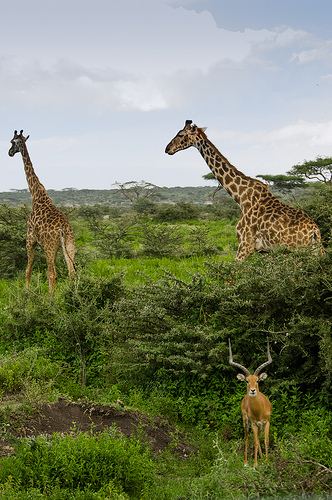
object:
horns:
[192, 125, 196, 132]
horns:
[19, 129, 24, 136]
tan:
[235, 182, 241, 189]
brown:
[260, 205, 266, 214]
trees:
[255, 156, 332, 218]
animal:
[162, 119, 325, 285]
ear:
[257, 373, 267, 381]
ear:
[236, 373, 246, 381]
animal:
[226, 338, 272, 468]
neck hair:
[185, 119, 262, 184]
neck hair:
[23, 138, 48, 194]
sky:
[0, 0, 332, 190]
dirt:
[16, 406, 180, 452]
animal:
[8, 129, 77, 292]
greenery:
[106, 238, 332, 419]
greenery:
[79, 176, 212, 257]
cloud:
[0, 0, 332, 189]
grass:
[0, 189, 332, 500]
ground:
[0, 197, 331, 496]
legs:
[251, 420, 259, 469]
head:
[237, 372, 268, 397]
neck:
[19, 144, 39, 198]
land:
[0, 184, 332, 500]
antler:
[225, 337, 250, 375]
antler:
[255, 336, 273, 376]